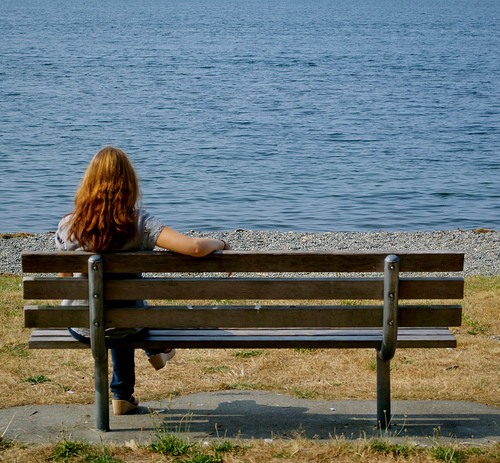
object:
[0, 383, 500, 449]
slab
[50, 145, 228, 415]
woman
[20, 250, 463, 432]
bench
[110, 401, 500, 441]
shadow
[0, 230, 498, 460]
ground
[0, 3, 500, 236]
water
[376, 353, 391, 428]
metal pole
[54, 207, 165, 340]
top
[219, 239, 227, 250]
watch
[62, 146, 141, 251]
hair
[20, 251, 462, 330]
back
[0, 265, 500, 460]
grass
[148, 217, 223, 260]
arm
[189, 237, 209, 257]
elbow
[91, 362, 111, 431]
metal pole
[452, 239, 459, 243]
gravel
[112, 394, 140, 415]
shoe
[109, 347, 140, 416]
leg